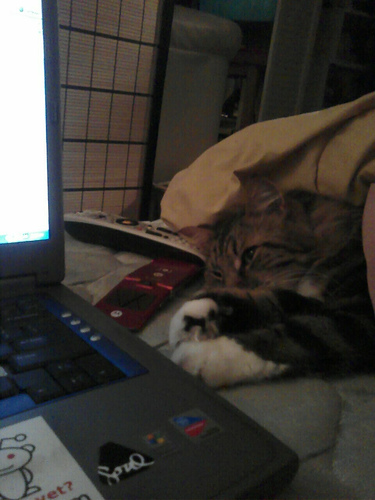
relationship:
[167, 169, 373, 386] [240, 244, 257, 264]
cat has eye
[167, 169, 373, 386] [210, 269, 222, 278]
cat has eye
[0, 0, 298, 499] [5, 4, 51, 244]
computer has screen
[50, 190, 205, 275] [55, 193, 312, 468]
control on bed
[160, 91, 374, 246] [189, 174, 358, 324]
blanket on cat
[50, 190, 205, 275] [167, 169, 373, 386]
control next cat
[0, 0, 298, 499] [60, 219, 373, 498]
computer on bed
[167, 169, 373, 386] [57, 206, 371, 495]
cat on mattress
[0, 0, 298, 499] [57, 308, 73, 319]
computer has button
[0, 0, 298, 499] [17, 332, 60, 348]
computer has button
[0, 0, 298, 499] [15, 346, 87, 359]
computer has button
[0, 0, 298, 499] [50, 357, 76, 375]
computer has button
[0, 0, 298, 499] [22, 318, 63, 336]
computer has button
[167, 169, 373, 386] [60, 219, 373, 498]
cat on bed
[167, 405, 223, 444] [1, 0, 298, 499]
sticker on computer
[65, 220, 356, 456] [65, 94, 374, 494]
matress on bed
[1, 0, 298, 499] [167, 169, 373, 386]
computer by cat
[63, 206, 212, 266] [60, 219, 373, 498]
remote on bed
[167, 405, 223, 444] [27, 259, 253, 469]
sticker on laptop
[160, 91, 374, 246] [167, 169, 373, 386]
blanket behind cat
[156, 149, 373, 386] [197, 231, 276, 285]
cat has eyes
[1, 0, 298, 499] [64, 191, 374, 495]
computer on bed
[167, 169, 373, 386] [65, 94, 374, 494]
cat on bed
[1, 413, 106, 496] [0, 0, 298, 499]
sticker on computer